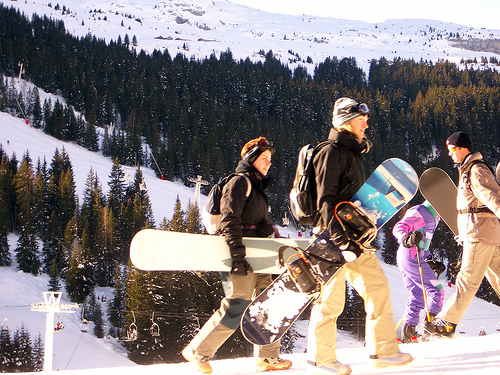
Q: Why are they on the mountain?
A: Snowboarding.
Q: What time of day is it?
A: Daytime.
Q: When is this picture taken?
A: On the mountain.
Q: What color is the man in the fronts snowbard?
A: Blue.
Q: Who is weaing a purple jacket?
A: Woman.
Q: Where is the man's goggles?
A: His head.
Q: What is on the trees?
A: Snow.